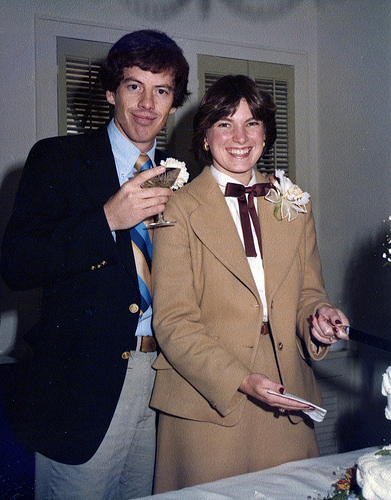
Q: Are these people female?
A: No, they are both male and female.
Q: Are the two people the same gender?
A: No, they are both male and female.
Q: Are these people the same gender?
A: No, they are both male and female.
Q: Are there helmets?
A: No, there are no helmets.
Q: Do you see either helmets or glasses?
A: No, there are no helmets or glasses.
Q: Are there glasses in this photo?
A: No, there are no glasses.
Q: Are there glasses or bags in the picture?
A: No, there are no glasses or bags.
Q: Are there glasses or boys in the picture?
A: No, there are no glasses or boys.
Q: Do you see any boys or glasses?
A: No, there are no glasses or boys.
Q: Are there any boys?
A: No, there are no boys.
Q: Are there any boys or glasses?
A: No, there are no boys or glasses.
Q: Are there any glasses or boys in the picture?
A: No, there are no boys or glasses.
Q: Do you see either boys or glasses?
A: No, there are no boys or glasses.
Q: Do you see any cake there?
A: Yes, there is a cake.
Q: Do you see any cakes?
A: Yes, there is a cake.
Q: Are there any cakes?
A: Yes, there is a cake.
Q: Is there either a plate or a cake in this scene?
A: Yes, there is a cake.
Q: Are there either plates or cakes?
A: Yes, there is a cake.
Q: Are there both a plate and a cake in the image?
A: No, there is a cake but no plates.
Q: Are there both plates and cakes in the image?
A: No, there is a cake but no plates.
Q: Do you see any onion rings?
A: No, there are no onion rings.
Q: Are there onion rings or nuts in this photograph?
A: No, there are no onion rings or nuts.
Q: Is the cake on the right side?
A: Yes, the cake is on the right of the image.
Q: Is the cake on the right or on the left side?
A: The cake is on the right of the image.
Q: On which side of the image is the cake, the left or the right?
A: The cake is on the right of the image.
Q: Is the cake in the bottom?
A: Yes, the cake is in the bottom of the image.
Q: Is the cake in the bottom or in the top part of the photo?
A: The cake is in the bottom of the image.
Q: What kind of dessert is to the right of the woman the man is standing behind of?
A: The dessert is a cake.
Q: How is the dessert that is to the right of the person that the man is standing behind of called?
A: The dessert is a cake.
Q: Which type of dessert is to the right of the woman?
A: The dessert is a cake.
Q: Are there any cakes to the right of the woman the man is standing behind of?
A: Yes, there is a cake to the right of the woman.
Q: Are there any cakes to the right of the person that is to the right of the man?
A: Yes, there is a cake to the right of the woman.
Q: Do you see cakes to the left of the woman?
A: No, the cake is to the right of the woman.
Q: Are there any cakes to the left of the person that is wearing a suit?
A: No, the cake is to the right of the woman.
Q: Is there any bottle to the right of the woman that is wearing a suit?
A: No, there is a cake to the right of the woman.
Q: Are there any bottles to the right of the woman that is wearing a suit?
A: No, there is a cake to the right of the woman.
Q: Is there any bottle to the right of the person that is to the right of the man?
A: No, there is a cake to the right of the woman.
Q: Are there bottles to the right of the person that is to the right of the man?
A: No, there is a cake to the right of the woman.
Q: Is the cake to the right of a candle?
A: No, the cake is to the right of the woman.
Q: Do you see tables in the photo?
A: Yes, there is a table.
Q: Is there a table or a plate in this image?
A: Yes, there is a table.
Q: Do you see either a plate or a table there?
A: Yes, there is a table.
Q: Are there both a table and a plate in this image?
A: No, there is a table but no plates.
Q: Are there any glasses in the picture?
A: No, there are no glasses.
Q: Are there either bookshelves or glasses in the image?
A: No, there are no glasses or bookshelves.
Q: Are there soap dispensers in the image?
A: No, there are no soap dispensers.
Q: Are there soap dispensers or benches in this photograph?
A: No, there are no soap dispensers or benches.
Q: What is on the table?
A: The flowers are on the table.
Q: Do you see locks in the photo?
A: No, there are no locks.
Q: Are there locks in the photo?
A: No, there are no locks.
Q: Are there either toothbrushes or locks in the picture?
A: No, there are no locks or toothbrushes.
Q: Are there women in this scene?
A: Yes, there is a woman.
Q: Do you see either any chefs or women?
A: Yes, there is a woman.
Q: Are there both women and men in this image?
A: Yes, there are both a woman and a man.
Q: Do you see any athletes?
A: No, there are no athletes.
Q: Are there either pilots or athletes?
A: No, there are no athletes or pilots.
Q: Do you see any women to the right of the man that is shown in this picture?
A: Yes, there is a woman to the right of the man.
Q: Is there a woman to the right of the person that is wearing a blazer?
A: Yes, there is a woman to the right of the man.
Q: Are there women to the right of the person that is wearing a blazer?
A: Yes, there is a woman to the right of the man.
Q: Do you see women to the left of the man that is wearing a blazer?
A: No, the woman is to the right of the man.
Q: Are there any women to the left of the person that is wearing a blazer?
A: No, the woman is to the right of the man.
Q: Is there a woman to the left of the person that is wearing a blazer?
A: No, the woman is to the right of the man.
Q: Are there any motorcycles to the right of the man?
A: No, there is a woman to the right of the man.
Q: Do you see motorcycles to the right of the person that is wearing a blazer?
A: No, there is a woman to the right of the man.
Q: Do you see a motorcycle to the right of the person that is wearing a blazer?
A: No, there is a woman to the right of the man.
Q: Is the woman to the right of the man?
A: Yes, the woman is to the right of the man.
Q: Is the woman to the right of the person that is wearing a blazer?
A: Yes, the woman is to the right of the man.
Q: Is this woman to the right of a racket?
A: No, the woman is to the right of the man.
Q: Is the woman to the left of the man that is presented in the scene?
A: No, the woman is to the right of the man.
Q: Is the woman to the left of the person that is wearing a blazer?
A: No, the woman is to the right of the man.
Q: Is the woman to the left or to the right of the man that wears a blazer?
A: The woman is to the right of the man.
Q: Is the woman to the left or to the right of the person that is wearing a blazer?
A: The woman is to the right of the man.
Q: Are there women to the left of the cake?
A: Yes, there is a woman to the left of the cake.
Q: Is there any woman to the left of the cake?
A: Yes, there is a woman to the left of the cake.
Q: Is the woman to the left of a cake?
A: Yes, the woman is to the left of a cake.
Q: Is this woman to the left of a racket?
A: No, the woman is to the left of a cake.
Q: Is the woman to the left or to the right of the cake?
A: The woman is to the left of the cake.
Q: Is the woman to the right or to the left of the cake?
A: The woman is to the left of the cake.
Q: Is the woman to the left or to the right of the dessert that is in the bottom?
A: The woman is to the left of the cake.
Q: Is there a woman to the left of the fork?
A: Yes, there is a woman to the left of the fork.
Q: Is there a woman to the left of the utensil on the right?
A: Yes, there is a woman to the left of the fork.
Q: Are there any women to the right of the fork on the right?
A: No, the woman is to the left of the fork.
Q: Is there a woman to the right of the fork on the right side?
A: No, the woman is to the left of the fork.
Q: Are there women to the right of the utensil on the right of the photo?
A: No, the woman is to the left of the fork.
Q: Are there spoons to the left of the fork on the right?
A: No, there is a woman to the left of the fork.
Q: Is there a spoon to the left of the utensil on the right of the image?
A: No, there is a woman to the left of the fork.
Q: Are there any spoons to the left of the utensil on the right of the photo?
A: No, there is a woman to the left of the fork.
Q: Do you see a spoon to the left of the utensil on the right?
A: No, there is a woman to the left of the fork.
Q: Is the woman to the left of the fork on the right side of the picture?
A: Yes, the woman is to the left of the fork.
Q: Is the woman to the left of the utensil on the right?
A: Yes, the woman is to the left of the fork.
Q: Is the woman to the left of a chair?
A: No, the woman is to the left of the fork.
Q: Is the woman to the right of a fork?
A: No, the woman is to the left of a fork.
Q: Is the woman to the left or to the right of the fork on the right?
A: The woman is to the left of the fork.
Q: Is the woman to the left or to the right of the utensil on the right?
A: The woman is to the left of the fork.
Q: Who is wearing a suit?
A: The woman is wearing a suit.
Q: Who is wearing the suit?
A: The woman is wearing a suit.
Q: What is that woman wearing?
A: The woman is wearing a suit.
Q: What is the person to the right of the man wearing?
A: The woman is wearing a suit.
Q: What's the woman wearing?
A: The woman is wearing a suit.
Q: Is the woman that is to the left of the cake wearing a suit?
A: Yes, the woman is wearing a suit.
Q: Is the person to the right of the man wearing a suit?
A: Yes, the woman is wearing a suit.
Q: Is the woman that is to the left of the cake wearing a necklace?
A: No, the woman is wearing a suit.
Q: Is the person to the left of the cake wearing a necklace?
A: No, the woman is wearing a suit.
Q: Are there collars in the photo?
A: Yes, there is a collar.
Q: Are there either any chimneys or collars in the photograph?
A: Yes, there is a collar.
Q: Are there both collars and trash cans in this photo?
A: No, there is a collar but no trash cans.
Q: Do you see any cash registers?
A: No, there are no cash registers.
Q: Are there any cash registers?
A: No, there are no cash registers.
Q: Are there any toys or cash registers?
A: No, there are no cash registers or toys.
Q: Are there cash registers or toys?
A: No, there are no cash registers or toys.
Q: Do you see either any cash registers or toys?
A: No, there are no cash registers or toys.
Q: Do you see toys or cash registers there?
A: No, there are no cash registers or toys.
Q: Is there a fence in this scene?
A: No, there are no fences.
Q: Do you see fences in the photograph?
A: No, there are no fences.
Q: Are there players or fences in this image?
A: No, there are no fences or players.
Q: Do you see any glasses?
A: No, there are no glasses.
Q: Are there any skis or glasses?
A: No, there are no glasses or skis.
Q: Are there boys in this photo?
A: No, there are no boys.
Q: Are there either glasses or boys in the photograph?
A: No, there are no boys or glasses.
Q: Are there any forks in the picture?
A: Yes, there is a fork.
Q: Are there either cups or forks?
A: Yes, there is a fork.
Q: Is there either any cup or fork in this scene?
A: Yes, there is a fork.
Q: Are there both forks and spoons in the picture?
A: No, there is a fork but no spoons.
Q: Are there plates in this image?
A: No, there are no plates.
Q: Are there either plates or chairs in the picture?
A: No, there are no plates or chairs.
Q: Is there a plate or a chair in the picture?
A: No, there are no plates or chairs.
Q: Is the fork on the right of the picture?
A: Yes, the fork is on the right of the image.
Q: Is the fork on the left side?
A: No, the fork is on the right of the image.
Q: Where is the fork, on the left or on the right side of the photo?
A: The fork is on the right of the image.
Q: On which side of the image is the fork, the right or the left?
A: The fork is on the right of the image.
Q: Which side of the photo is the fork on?
A: The fork is on the right of the image.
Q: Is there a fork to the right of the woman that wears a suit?
A: Yes, there is a fork to the right of the woman.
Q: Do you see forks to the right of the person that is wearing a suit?
A: Yes, there is a fork to the right of the woman.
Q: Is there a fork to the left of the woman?
A: No, the fork is to the right of the woman.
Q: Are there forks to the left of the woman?
A: No, the fork is to the right of the woman.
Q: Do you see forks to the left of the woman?
A: No, the fork is to the right of the woman.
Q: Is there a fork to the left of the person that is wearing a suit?
A: No, the fork is to the right of the woman.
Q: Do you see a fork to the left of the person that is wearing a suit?
A: No, the fork is to the right of the woman.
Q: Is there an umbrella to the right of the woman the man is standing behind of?
A: No, there is a fork to the right of the woman.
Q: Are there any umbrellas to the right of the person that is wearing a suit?
A: No, there is a fork to the right of the woman.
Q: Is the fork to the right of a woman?
A: Yes, the fork is to the right of a woman.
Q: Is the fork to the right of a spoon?
A: No, the fork is to the right of a woman.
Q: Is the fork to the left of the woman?
A: No, the fork is to the right of the woman.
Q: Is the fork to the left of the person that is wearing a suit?
A: No, the fork is to the right of the woman.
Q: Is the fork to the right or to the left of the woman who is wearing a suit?
A: The fork is to the right of the woman.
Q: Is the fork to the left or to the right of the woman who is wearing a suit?
A: The fork is to the right of the woman.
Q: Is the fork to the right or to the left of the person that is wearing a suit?
A: The fork is to the right of the woman.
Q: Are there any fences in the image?
A: No, there are no fences.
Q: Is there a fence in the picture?
A: No, there are no fences.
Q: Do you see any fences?
A: No, there are no fences.